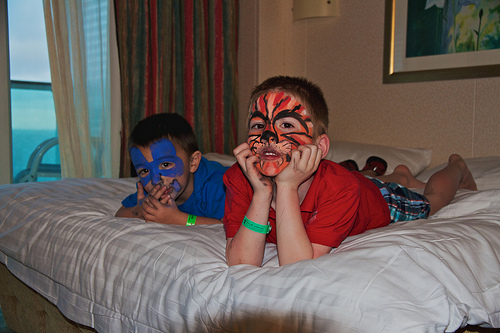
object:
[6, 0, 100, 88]
window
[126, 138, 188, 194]
face paint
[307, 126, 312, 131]
orange paint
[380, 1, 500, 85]
pitcher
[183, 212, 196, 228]
wrist band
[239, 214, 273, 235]
wrist band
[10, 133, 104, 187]
chair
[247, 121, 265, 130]
right eye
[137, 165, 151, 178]
right eye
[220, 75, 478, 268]
boy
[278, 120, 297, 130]
eye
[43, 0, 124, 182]
curtains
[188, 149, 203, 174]
ear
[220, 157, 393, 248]
shirt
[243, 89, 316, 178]
face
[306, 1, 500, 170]
wall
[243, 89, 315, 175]
face paint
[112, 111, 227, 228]
boy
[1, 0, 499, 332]
room